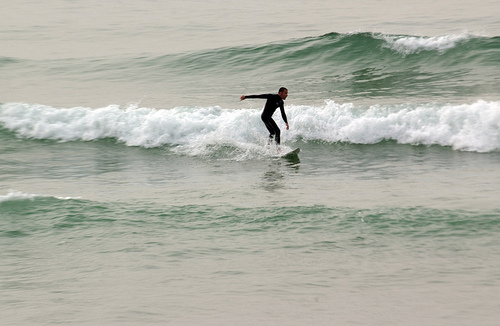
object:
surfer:
[239, 86, 290, 149]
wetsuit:
[242, 93, 287, 147]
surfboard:
[270, 146, 301, 161]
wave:
[1, 100, 499, 162]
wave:
[146, 30, 499, 87]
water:
[0, 0, 500, 326]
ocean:
[0, 1, 500, 324]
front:
[282, 146, 303, 158]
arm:
[247, 93, 278, 99]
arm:
[278, 101, 291, 123]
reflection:
[261, 145, 286, 192]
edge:
[278, 149, 299, 160]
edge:
[1, 131, 500, 160]